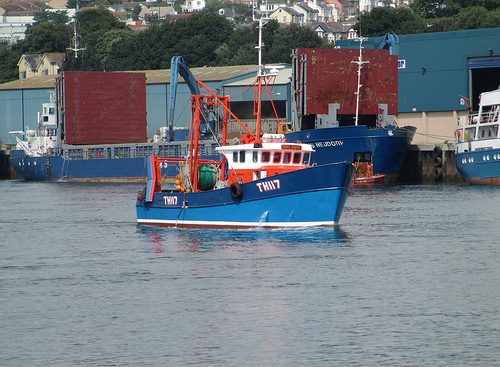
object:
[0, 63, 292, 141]
blue building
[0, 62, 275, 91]
brown roof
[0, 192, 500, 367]
spot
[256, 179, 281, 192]
numbers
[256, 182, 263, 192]
letter t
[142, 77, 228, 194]
equipment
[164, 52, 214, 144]
crain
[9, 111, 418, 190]
boat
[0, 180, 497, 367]
water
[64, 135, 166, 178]
wall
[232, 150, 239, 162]
window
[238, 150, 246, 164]
window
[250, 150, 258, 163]
window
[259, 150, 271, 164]
window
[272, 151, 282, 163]
window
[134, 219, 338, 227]
white color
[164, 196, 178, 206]
numbers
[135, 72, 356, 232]
boat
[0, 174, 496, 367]
lake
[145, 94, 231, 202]
orange equipment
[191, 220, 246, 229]
color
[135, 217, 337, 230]
boar